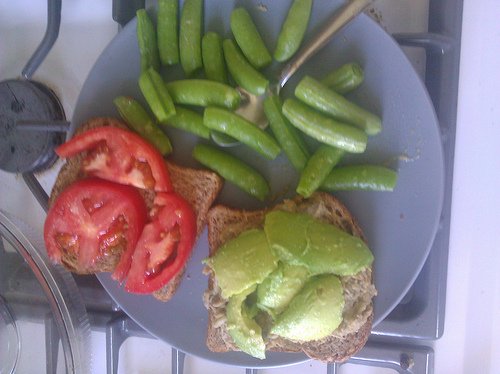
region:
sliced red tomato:
[42, 123, 197, 295]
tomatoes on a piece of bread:
[38, 113, 220, 312]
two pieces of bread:
[41, 113, 384, 370]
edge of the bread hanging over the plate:
[307, 340, 372, 365]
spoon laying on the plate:
[202, 0, 384, 155]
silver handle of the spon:
[284, 0, 369, 92]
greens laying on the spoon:
[184, 79, 295, 158]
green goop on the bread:
[202, 195, 388, 362]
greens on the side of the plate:
[106, 0, 426, 217]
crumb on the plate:
[393, 210, 415, 224]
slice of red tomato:
[128, 196, 203, 300]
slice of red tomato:
[55, 126, 172, 198]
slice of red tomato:
[36, 175, 139, 286]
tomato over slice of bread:
[38, 120, 217, 307]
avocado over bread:
[194, 184, 379, 369]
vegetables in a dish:
[46, 3, 453, 373]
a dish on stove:
[1, 2, 498, 372]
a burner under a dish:
[31, 3, 465, 372]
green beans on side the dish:
[151, 4, 406, 191]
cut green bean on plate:
[293, 75, 385, 136]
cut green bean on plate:
[278, 100, 370, 159]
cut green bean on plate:
[290, 142, 342, 198]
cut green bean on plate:
[328, 164, 395, 194]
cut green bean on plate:
[258, 90, 309, 164]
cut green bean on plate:
[323, 62, 366, 94]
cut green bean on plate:
[204, 106, 275, 159]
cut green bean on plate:
[192, 143, 274, 201]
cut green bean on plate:
[108, 90, 167, 159]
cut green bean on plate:
[137, 65, 173, 125]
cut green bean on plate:
[132, 6, 160, 73]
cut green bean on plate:
[153, 2, 183, 69]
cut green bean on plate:
[178, 1, 204, 77]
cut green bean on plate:
[201, 27, 224, 78]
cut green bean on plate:
[222, 36, 269, 101]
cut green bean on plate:
[227, 2, 270, 68]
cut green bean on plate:
[270, 0, 310, 65]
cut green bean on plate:
[292, 77, 379, 137]